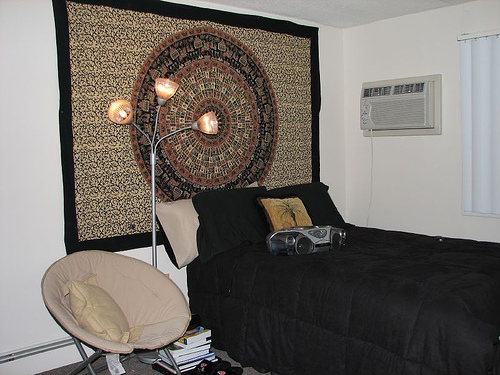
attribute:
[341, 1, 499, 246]
wall — white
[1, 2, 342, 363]
wall — white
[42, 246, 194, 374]
chair — beige, tan, round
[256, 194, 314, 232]
pillow — tan, square, black, small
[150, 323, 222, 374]
books — heaped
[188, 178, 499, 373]
bedding — dark, black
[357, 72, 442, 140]
air conditioner — unit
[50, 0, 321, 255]
rug — large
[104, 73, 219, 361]
lamp — tall, flexible, silver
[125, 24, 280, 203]
design — round, circular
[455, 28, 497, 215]
blinds — vertical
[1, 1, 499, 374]
bedroom — nice, small, comfy, personal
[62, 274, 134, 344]
pillow — tan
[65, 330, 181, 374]
legs — crossed, metal, silver